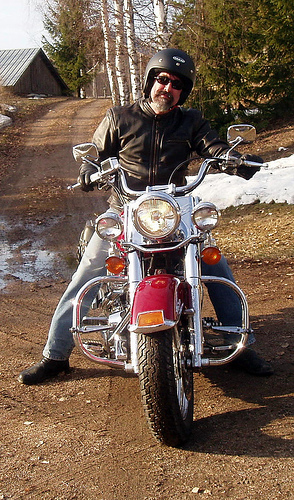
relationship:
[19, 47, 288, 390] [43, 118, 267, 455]
man on motorcycle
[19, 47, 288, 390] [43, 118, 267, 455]
man riding motorcycle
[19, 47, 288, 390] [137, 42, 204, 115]
man wearing helmet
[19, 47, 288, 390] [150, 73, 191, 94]
man wearing sunglasses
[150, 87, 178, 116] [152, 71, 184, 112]
hair on face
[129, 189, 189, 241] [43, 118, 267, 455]
headlight of motorcycle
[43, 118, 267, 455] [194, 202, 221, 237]
motorcycle turn signal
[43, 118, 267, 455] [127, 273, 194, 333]
motorcycle front fender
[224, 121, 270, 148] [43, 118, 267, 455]
mirror of motorcycle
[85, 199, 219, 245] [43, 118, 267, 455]
lights on bike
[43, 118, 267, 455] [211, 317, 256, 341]
bike foot rest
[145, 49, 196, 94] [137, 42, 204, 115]
head in helmet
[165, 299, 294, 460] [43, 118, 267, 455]
shadow of bike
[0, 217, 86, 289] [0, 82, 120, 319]
water on road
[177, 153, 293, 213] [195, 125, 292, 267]
snow on ground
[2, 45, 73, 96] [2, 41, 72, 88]
barn has a roof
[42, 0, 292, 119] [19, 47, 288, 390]
trees behind man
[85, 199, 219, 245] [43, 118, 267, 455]
headlights on motorcycle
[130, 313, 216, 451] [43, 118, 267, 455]
wheel on motorcycle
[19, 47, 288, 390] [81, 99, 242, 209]
man wearing jacket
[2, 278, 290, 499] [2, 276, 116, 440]
dirt has tracks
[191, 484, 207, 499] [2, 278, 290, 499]
stone on dirt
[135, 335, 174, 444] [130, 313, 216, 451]
grooves in wheel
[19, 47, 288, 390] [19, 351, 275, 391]
man wearing shoes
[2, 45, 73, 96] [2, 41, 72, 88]
house has rooftop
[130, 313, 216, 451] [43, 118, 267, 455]
tires on motorcycle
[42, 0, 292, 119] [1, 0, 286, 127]
trees in background